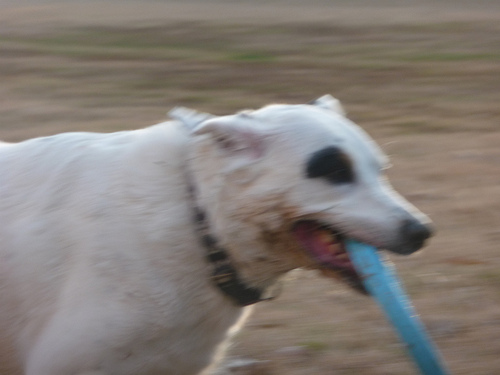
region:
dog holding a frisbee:
[2, 40, 472, 370]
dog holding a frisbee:
[65, 53, 485, 367]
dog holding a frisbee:
[31, 55, 452, 370]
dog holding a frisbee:
[18, 63, 468, 374]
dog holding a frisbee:
[21, 51, 473, 373]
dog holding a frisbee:
[21, 47, 457, 372]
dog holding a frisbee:
[44, 81, 477, 373]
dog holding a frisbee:
[35, 82, 469, 368]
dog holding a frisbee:
[16, 65, 471, 370]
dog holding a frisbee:
[6, 49, 451, 372]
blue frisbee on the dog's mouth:
[344, 240, 449, 373]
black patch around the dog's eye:
[304, 145, 354, 183]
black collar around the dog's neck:
[181, 111, 265, 304]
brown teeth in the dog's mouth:
[319, 227, 351, 269]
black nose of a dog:
[404, 221, 435, 240]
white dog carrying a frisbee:
[1, 94, 433, 374]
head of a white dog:
[191, 95, 430, 293]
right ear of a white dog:
[190, 115, 278, 152]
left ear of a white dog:
[316, 93, 342, 115]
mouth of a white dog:
[296, 178, 433, 294]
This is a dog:
[17, 88, 406, 353]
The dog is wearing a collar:
[167, 120, 267, 308]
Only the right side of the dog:
[12, 85, 416, 347]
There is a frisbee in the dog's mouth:
[336, 214, 468, 369]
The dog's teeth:
[312, 216, 345, 258]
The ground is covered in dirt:
[29, 57, 489, 349]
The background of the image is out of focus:
[10, 10, 488, 355]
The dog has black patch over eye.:
[304, 137, 369, 195]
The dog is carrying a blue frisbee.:
[340, 242, 440, 344]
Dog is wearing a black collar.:
[181, 177, 238, 291]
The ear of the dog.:
[179, 105, 266, 149]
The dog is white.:
[35, 129, 299, 371]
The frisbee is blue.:
[362, 254, 432, 340]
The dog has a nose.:
[395, 214, 440, 249]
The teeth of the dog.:
[320, 227, 355, 257]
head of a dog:
[189, 65, 446, 319]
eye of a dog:
[299, 132, 373, 192]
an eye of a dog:
[313, 138, 367, 180]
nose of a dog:
[387, 198, 449, 250]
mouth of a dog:
[289, 223, 409, 288]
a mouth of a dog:
[290, 226, 405, 277]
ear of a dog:
[185, 103, 269, 167]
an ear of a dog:
[186, 93, 294, 158]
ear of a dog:
[302, 76, 356, 127]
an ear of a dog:
[306, 93, 351, 133]